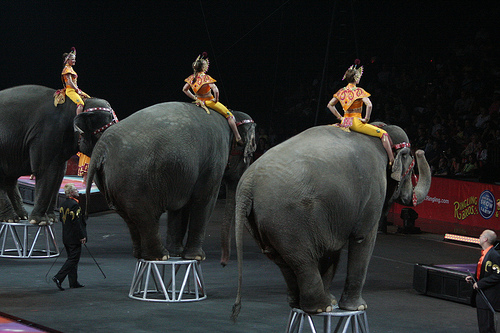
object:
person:
[326, 59, 395, 166]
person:
[182, 51, 247, 145]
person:
[53, 47, 91, 132]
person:
[51, 183, 87, 291]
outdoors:
[1, 46, 499, 332]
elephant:
[229, 120, 433, 325]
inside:
[0, 220, 62, 258]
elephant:
[0, 85, 120, 226]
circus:
[0, 48, 499, 332]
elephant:
[87, 101, 258, 261]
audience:
[453, 149, 476, 179]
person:
[455, 128, 469, 143]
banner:
[386, 175, 499, 240]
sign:
[452, 189, 499, 220]